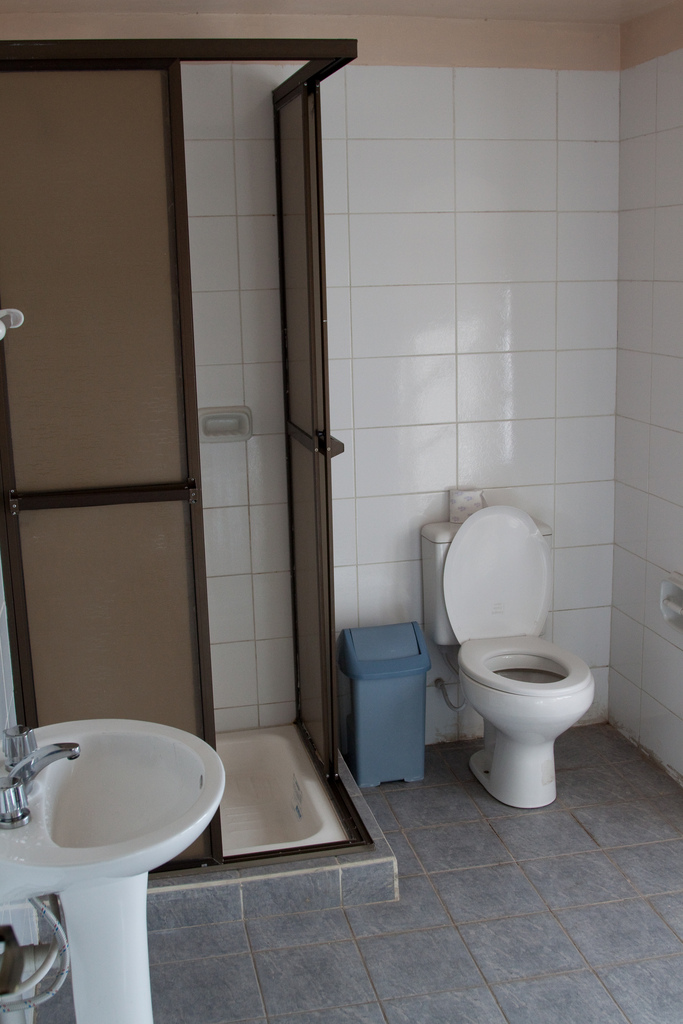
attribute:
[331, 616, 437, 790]
trash can — blue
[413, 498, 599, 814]
toilet — white, bathroom toilet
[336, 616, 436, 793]
garbage can — blue, plastic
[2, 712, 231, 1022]
sink — white, pedestal, bathroom sink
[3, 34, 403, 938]
shower — a stand up shower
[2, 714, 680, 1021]
flooring — tiled, dark grey